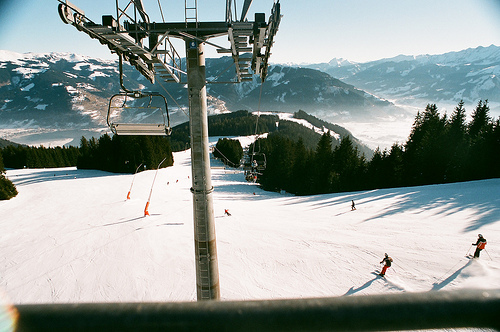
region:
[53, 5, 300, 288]
gray ski lift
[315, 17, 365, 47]
white clouds in blue sky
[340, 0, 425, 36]
white clouds in blue sky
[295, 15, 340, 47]
white clouds in blue skys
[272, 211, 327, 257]
white snow on hill side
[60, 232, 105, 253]
white snow on hill side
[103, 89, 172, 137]
Empty seat of the ski lift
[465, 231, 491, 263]
A skier going down the hill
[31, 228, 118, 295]
White snow on the side of a mountain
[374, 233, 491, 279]
Two skiers making their way downhill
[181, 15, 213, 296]
Maintenance ladder on the ski lift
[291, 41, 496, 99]
Mountains in the distance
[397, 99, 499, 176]
Pine trees on the side of the mountain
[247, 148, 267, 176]
Person coming up the mountain in a ski lift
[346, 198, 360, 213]
Person sliding down the hill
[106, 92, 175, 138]
Empty seat of a ski lift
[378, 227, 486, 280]
People skiing down a slope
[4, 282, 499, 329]
A gray metal pole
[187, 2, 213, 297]
A tall ladder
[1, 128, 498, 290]
A snow covered hill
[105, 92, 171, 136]
A ski lift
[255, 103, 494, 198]
A line of pine trees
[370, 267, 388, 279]
A pair of skis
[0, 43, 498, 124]
Snowy mountains in front of the hill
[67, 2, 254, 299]
A tall ski lift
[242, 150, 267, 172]
A person sitting on the ski lift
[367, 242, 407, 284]
this is a person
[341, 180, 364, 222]
this is a person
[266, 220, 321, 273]
this is ice on the ground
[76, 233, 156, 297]
this is ice on the ground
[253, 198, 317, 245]
this is ice on the ground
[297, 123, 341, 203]
this is a tree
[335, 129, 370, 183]
this is a tree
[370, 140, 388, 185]
this is a tree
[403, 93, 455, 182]
this is a tree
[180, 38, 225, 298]
large thick gray metal pole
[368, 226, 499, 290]
two skiers skiing in snow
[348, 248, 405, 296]
one skier casting shadow in snow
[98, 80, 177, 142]
one black metal ski lift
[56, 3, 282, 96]
gray metal ski lift mechanism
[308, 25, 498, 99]
snow covered mountain against bright sky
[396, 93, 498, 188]
several shadowed green trees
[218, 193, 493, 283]
several people on snow covered slope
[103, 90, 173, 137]
one empty ski lift chair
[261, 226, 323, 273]
Large body of snow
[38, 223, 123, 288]
Large body of snow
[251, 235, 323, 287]
Large body of snow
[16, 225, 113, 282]
Large body of snow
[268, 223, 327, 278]
Large body of snow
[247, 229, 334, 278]
Large body of snow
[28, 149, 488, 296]
snow on the ground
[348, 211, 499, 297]
a pair of people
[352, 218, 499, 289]
the people are skiing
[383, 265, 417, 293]
tracks in the snow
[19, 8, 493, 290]
a bright and clear day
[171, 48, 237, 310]
a large gray pole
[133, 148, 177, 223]
posts in the snow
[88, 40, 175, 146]
ski lift in the air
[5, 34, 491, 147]
mountains in the background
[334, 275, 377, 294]
shadow on the ground